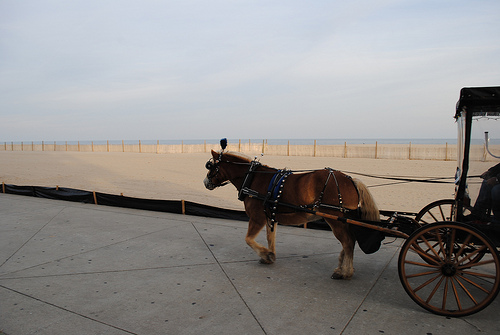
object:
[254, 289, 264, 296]
dot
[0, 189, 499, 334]
cement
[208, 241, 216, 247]
dot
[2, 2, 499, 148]
sky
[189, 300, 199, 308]
dot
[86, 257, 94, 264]
dot